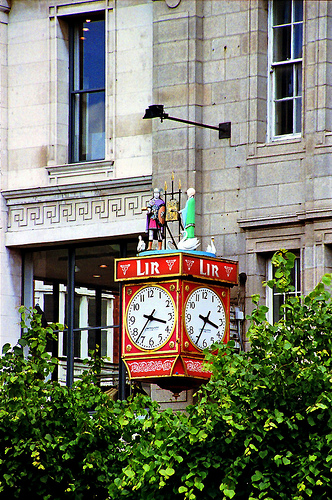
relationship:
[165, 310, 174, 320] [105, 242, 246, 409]
number on clock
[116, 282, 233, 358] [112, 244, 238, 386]
clock with face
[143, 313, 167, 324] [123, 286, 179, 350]
hand on clock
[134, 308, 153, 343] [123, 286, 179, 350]
hand on clock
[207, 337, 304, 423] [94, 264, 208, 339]
foilage in front of clock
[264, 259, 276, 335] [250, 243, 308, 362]
white frame of window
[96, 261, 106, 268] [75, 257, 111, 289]
lighting on ceiling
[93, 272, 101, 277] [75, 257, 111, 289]
lighting on ceiling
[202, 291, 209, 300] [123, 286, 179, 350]
number on clock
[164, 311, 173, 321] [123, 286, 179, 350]
black number on clock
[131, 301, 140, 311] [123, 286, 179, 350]
number on clock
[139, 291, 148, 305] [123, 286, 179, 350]
black number on clock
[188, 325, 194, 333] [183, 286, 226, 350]
number on clock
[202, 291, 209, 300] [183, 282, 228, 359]
number on clock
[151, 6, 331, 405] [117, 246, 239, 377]
building with a clock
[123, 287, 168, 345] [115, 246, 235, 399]
3:37 shown on clock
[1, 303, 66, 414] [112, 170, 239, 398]
shrub growing near clock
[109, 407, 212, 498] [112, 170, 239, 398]
shrub growing near clock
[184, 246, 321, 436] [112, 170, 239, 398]
shrub growing near clock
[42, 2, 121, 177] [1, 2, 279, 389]
window belonging to building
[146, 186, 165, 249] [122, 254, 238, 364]
figurine standing on top of clockk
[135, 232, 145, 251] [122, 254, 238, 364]
figurine standing on top of clockk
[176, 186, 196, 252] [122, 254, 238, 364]
figurine standing on top of clockk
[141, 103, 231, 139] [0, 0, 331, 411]
protruding light mounted on building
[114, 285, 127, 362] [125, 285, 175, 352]
edge belonging to clock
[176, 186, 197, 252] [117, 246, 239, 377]
figurine on clock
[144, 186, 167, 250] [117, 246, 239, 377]
figurine on clock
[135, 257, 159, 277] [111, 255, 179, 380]
lir on side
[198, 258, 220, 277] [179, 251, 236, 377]
lir on side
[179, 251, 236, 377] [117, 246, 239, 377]
side of clock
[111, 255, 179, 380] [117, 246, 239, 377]
side of clock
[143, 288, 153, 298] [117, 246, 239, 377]
number on clock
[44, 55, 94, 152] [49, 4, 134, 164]
edge on window